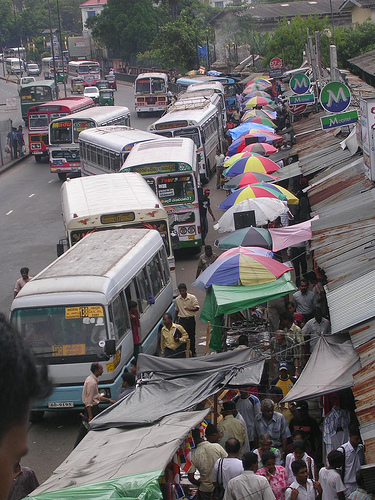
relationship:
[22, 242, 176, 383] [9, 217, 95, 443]
bus on street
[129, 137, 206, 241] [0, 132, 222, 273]
bus on street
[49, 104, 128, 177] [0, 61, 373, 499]
bus on street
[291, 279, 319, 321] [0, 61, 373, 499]
people on street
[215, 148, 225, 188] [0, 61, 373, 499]
people on street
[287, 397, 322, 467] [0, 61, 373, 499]
people on street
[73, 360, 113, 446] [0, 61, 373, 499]
people on street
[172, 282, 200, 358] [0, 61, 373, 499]
man on street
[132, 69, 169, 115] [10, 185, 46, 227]
bus on street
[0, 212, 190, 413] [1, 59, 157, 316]
bus on street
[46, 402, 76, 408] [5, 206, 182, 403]
plate on bus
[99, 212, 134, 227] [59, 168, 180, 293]
sign on bus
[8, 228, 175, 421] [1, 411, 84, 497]
bus in street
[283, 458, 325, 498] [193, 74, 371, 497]
shopper in market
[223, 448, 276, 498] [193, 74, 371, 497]
shopper in market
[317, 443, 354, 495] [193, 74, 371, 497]
shopper in market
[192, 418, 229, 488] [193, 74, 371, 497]
shopper in market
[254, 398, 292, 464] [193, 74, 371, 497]
man in market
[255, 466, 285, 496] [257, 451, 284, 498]
pink shirt on woman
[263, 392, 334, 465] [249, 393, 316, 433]
shirt on man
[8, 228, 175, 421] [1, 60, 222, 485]
bus on road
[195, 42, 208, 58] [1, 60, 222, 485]
banner next to road